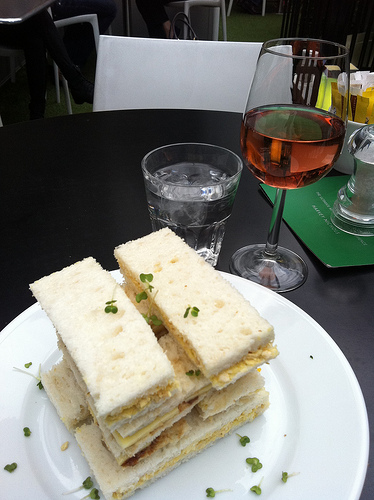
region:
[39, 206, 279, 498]
food on a plate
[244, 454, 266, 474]
small watercress leaf on a plate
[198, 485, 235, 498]
small watercress leaf on a plate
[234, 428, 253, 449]
small watercress leaf on a plate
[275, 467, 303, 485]
small watercress leaf on a plate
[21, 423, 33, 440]
small watercress leaf on a plate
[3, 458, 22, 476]
small watercress leaf on a plate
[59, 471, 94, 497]
small watercress leaf on a plate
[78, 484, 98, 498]
small watercress leaf on a plate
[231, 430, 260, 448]
Green plant on white plate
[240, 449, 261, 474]
Green plant on white plate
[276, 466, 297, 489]
Green plant on white plate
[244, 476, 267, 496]
Green plant on white plate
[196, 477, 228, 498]
Green plant on white plate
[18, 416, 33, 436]
Green plant on white plate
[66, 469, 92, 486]
Green plant on white plate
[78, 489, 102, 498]
Green plant on white plate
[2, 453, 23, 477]
Green plant on white plate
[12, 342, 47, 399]
Green plant on white plate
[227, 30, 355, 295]
glass of a drink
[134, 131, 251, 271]
a glass of water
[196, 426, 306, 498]
condiments on a plate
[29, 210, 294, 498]
small slices of sandwich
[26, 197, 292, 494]
sandwiches stacked on top of each other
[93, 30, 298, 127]
a white chair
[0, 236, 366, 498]
a white plate of sandwiches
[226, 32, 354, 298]
a glass of sweet wine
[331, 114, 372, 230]
a bottle of spice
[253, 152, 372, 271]
a menu on a table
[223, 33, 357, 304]
rose wine in glass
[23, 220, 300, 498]
stack of egg salad sandwiches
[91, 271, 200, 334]
green garnish on top of sandwiches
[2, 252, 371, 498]
round white ceramic plate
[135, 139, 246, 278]
drinking glass with water and ice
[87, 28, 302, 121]
top of back of white chair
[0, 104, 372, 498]
round black table top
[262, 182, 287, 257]
glass stem of wine glass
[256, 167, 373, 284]
green paper menu on table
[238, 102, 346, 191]
rose wine in wine glass